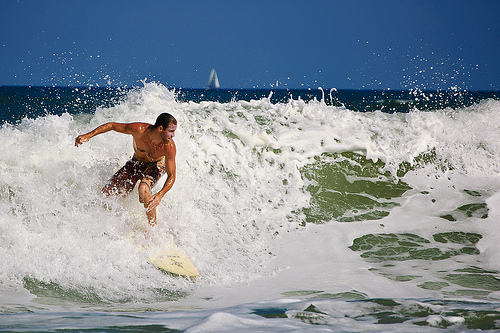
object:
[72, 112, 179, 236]
man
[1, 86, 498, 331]
water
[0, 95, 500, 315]
wave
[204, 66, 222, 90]
sailboat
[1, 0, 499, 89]
sky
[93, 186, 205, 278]
surfboard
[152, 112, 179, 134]
hair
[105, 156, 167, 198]
shorts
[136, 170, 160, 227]
bare legs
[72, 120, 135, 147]
arms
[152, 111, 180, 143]
head